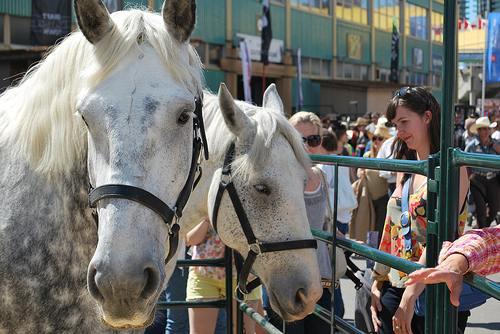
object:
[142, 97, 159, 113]
dots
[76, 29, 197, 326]
face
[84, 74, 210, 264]
bridle strap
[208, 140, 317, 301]
bridle strap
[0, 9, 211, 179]
hair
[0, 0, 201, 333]
horse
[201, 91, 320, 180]
hair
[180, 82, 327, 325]
horse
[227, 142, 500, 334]
railing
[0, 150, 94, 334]
pattern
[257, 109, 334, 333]
woman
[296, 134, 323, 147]
sunglasses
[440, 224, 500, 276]
sleeve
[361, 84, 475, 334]
woman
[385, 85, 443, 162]
hair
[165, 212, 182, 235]
ring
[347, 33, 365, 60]
sign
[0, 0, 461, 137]
building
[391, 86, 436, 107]
sunglasses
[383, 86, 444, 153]
head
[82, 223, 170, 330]
nose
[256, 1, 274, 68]
flag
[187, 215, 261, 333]
girl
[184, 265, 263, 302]
shorts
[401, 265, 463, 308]
hand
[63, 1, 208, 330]
head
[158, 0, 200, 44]
ears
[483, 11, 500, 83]
flag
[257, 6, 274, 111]
pole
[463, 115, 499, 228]
man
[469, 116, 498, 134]
hat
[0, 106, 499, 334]
pen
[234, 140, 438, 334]
gate